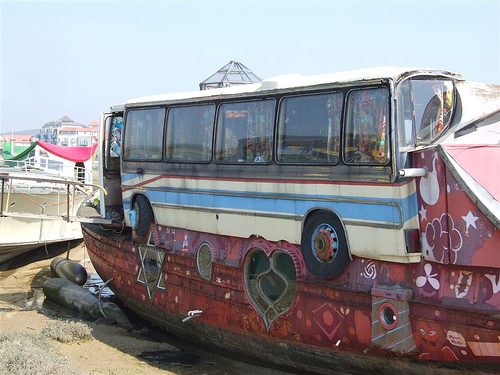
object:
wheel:
[300, 211, 348, 279]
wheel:
[131, 193, 153, 237]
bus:
[97, 67, 480, 281]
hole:
[328, 229, 335, 233]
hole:
[332, 238, 338, 243]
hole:
[322, 225, 327, 229]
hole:
[332, 248, 337, 252]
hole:
[328, 255, 333, 260]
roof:
[37, 140, 97, 163]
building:
[0, 140, 99, 194]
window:
[47, 160, 64, 172]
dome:
[199, 58, 265, 90]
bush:
[0, 328, 61, 374]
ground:
[1, 239, 302, 375]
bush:
[42, 318, 94, 344]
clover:
[414, 262, 439, 290]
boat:
[80, 70, 499, 374]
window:
[122, 106, 164, 163]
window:
[164, 103, 214, 163]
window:
[214, 98, 277, 164]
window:
[340, 86, 394, 166]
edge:
[376, 302, 400, 331]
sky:
[2, 0, 500, 135]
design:
[310, 302, 343, 341]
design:
[425, 213, 464, 265]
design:
[359, 258, 377, 279]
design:
[419, 149, 440, 206]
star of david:
[135, 222, 167, 305]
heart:
[239, 240, 308, 336]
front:
[99, 97, 169, 237]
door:
[101, 106, 124, 222]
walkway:
[0, 171, 108, 246]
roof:
[2, 142, 38, 167]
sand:
[2, 321, 299, 373]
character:
[418, 315, 460, 363]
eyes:
[417, 327, 437, 337]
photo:
[0, 0, 499, 375]